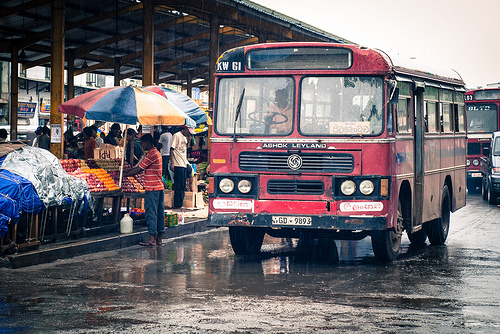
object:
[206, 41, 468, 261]
bus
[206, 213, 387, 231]
black bumper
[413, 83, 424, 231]
door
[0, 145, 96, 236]
tarps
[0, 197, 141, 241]
table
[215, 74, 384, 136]
windshield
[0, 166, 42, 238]
blue tarp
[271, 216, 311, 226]
license plate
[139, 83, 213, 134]
umbrella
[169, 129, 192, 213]
man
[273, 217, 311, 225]
lettering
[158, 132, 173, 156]
shirt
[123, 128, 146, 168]
man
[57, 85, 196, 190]
umbrellas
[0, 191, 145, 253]
fruit stand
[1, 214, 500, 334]
road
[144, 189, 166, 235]
pants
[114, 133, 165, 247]
man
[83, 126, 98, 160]
person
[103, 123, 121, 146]
person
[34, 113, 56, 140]
person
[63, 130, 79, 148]
person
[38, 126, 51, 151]
person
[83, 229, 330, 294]
water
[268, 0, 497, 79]
skies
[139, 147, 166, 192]
shirt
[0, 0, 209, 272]
market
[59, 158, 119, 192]
fruit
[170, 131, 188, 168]
shirt